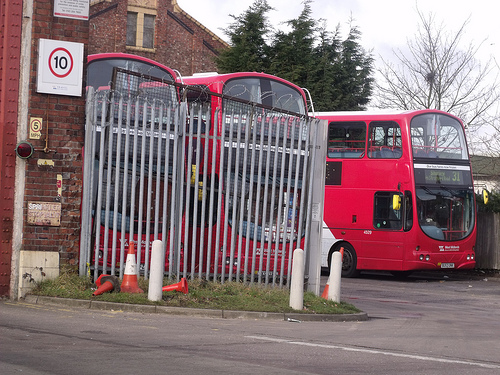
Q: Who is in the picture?
A: No one.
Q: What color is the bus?
A: Red.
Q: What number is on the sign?
A: 10.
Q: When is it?
A: Day time.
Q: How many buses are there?
A: 3.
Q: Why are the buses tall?
A: They are double decker buses.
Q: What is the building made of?
A: Brick.